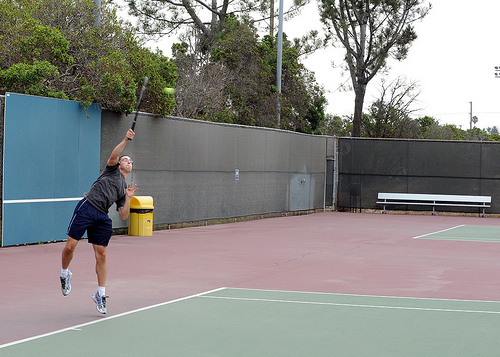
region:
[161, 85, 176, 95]
A moving tennis ball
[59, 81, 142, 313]
A man playing tennis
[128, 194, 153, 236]
A yellow garbage can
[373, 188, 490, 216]
A long metal bench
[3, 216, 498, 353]
A tennis court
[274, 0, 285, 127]
A tall metal pole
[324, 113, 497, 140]
The tops of trees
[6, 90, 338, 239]
A tall fence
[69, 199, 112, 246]
Dark blue shorts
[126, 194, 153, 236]
A garbage can with a black bag in it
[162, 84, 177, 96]
A yellow ball in the air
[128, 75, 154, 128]
A racket sticking out in the air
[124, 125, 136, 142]
A fist in the air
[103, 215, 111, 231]
A bulging left pocket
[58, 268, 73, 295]
A foot in the air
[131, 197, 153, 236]
A yellow trash container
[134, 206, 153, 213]
A black strip of polythene paper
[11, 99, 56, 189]
A blue wall surface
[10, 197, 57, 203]
A white line on a blue surface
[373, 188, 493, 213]
A white bench in the corner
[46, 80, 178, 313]
man leaping to hit ball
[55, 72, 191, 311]
aggressively playing a game of tennis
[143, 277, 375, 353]
tennis court is green and red with white painted boundary lines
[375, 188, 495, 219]
empty metal bench against a fence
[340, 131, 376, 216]
tall black metal fencing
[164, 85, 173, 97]
green tennis ball in motion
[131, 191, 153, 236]
yellow trashcan with black liner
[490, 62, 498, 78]
stadium lighting on a overlooking the court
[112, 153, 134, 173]
man is wearing a pair of glasses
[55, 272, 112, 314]
white and grey tennis shoes with white socks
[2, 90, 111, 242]
blue part of wall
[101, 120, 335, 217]
grey part of wall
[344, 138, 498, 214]
black part of wall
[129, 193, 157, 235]
yellow trash can by wall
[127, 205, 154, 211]
black bag in trash can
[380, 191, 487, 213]
bench by black wall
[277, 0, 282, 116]
black pole behind wall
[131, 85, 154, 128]
black racket in hand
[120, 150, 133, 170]
face looking at ball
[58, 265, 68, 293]
grey and white shoe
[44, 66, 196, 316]
tennis player hitting a ball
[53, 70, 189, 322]
tennis player jumping in the air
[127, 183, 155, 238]
yellow trash can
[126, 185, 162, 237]
trash can has a black plastic bag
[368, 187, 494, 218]
a long bench on side of tennis court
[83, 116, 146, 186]
person wears glasses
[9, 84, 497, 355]
tennis court is fenced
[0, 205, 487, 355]
tennis court is green and red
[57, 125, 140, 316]
tennis player wears blue shorts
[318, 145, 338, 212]
door of tennis court